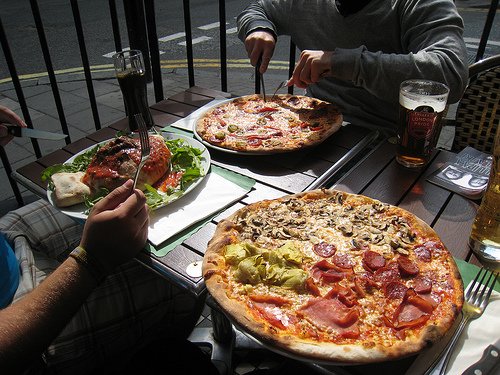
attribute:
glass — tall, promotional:
[395, 78, 450, 170]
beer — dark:
[396, 99, 447, 164]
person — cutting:
[236, 1, 469, 140]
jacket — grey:
[237, 0, 468, 131]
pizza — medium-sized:
[196, 92, 345, 156]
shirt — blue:
[0, 235, 21, 309]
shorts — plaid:
[1, 200, 198, 375]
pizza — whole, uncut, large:
[203, 189, 466, 365]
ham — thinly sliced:
[250, 261, 432, 342]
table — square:
[9, 83, 380, 298]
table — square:
[203, 137, 499, 374]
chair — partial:
[432, 52, 499, 155]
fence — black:
[0, 0, 499, 206]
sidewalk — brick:
[2, 74, 202, 214]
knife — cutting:
[256, 58, 267, 101]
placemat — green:
[148, 167, 259, 258]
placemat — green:
[454, 254, 499, 299]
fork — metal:
[421, 266, 498, 373]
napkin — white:
[404, 277, 499, 373]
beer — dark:
[116, 67, 152, 130]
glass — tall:
[112, 50, 154, 132]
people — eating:
[0, 0, 470, 374]